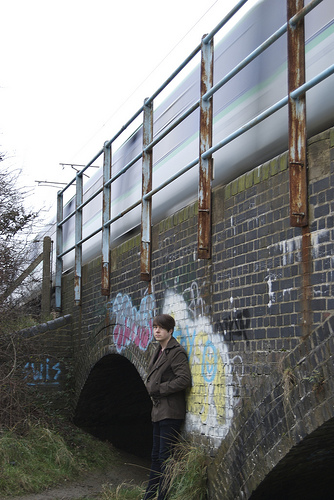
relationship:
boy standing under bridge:
[141, 314, 191, 500] [9, 0, 331, 496]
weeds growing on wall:
[2, 341, 54, 428] [8, 127, 332, 496]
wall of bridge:
[8, 127, 332, 496] [9, 0, 331, 496]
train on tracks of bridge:
[35, 0, 333, 280] [1, 240, 332, 498]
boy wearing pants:
[141, 314, 191, 500] [142, 417, 182, 497]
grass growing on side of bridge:
[124, 421, 218, 497] [9, 0, 331, 496]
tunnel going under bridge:
[75, 328, 159, 460] [4, 8, 324, 466]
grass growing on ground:
[10, 428, 64, 472] [1, 414, 151, 498]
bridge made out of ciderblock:
[9, 0, 331, 496] [230, 208, 259, 226]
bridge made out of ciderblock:
[9, 0, 331, 496] [270, 318, 278, 328]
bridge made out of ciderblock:
[9, 0, 331, 496] [263, 316, 271, 325]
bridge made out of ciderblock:
[9, 0, 331, 496] [284, 314, 292, 324]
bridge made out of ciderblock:
[9, 0, 331, 496] [250, 319, 258, 327]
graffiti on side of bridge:
[105, 281, 243, 455] [33, 60, 332, 489]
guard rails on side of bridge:
[55, 0, 332, 310] [0, 126, 332, 498]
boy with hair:
[141, 314, 191, 500] [148, 313, 176, 331]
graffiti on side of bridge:
[110, 292, 242, 440] [9, 0, 331, 496]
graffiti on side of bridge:
[23, 358, 61, 385] [9, 0, 331, 496]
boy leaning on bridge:
[141, 313, 190, 498] [9, 0, 331, 496]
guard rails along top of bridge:
[55, 0, 334, 313] [0, 126, 332, 498]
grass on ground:
[0, 380, 117, 494] [1, 414, 151, 498]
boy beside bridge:
[141, 314, 191, 500] [9, 0, 331, 496]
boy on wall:
[141, 314, 191, 500] [8, 127, 332, 496]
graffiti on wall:
[110, 292, 242, 440] [57, 272, 303, 459]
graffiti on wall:
[20, 356, 66, 387] [57, 272, 303, 459]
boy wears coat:
[141, 314, 191, 500] [141, 336, 195, 421]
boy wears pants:
[141, 314, 191, 500] [142, 417, 182, 497]